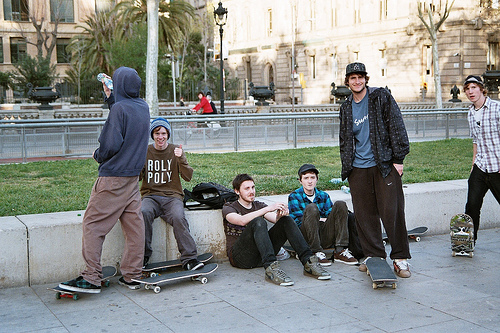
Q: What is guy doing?
A: Drinking.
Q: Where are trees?
A: In background.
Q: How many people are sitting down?
A: Two.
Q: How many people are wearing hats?
A: Three.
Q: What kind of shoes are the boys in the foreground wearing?
A: Sneakers.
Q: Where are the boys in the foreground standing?
A: Sidewalk.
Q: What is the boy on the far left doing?
A: Drinking from plastic bottle.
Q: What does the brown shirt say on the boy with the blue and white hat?
A: Roly poly.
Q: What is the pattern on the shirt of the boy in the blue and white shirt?
A: Plaid.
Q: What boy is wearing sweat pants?
A: The second boy from the right.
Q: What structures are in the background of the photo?
A: Buildings.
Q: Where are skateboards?
A: On the ground.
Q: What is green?
A: Grass.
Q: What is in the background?
A: Buildings.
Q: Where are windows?
A: On buildings.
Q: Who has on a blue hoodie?
A: Guy on left.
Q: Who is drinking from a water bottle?
A: Boy on the left.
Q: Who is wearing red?
A: Person in the background.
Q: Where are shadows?
A: On the building.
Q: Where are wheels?
A: On skateboards.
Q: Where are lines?
A: On the ground.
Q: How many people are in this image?
A: Seven.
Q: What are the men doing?
A: Standing and sitting.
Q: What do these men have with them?
A: Skateboards.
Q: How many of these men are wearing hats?
A: Five.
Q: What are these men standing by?
A: A pole.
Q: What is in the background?
A: A building.